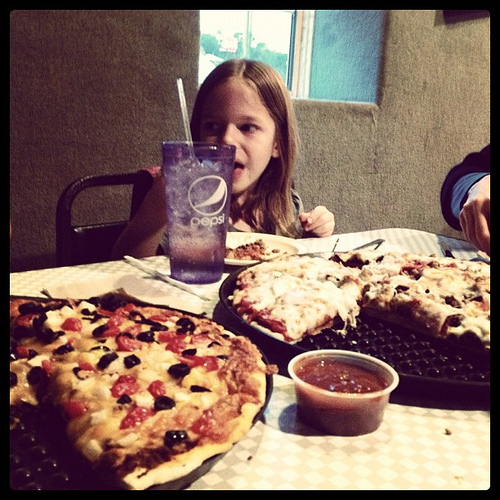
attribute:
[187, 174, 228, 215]
logo — pepsi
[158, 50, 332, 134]
hair — blonde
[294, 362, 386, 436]
sauce — dipping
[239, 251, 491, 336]
pizza — cheese, pie